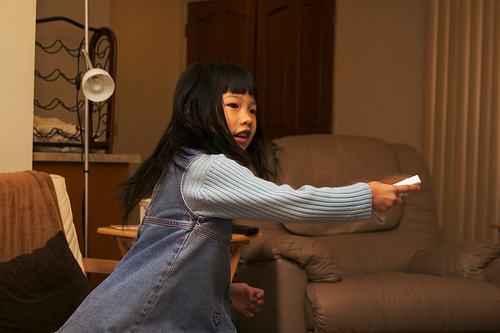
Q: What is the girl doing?
A: Playing Wii.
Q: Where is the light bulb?
A: On the left hand side.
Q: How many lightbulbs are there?
A: One.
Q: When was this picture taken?
A: When the girl was playing video games.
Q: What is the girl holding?
A: A Wii remote.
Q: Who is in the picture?
A: A little girl.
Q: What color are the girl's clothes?
A: Blue.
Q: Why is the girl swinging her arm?
A: She's playing a video game.